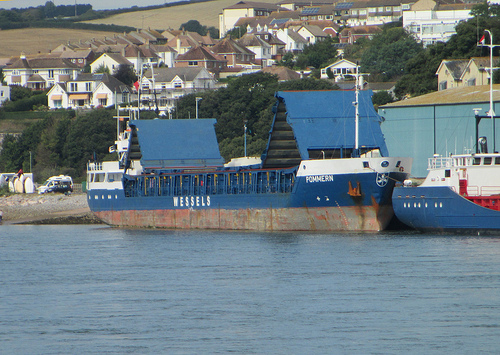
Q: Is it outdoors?
A: Yes, it is outdoors.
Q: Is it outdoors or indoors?
A: It is outdoors.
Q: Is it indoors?
A: No, it is outdoors.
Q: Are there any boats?
A: Yes, there is a boat.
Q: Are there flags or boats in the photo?
A: Yes, there is a boat.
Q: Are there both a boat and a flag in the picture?
A: Yes, there are both a boat and a flag.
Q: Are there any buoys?
A: No, there are no buoys.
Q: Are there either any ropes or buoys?
A: No, there are no buoys or ropes.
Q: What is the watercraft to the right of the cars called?
A: The watercraft is a boat.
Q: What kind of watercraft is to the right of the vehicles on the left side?
A: The watercraft is a boat.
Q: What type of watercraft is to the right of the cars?
A: The watercraft is a boat.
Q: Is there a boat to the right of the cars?
A: Yes, there is a boat to the right of the cars.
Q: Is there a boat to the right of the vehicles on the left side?
A: Yes, there is a boat to the right of the cars.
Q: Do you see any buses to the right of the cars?
A: No, there is a boat to the right of the cars.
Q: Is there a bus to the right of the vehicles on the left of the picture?
A: No, there is a boat to the right of the cars.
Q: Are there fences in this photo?
A: No, there are no fences.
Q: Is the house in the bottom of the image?
A: No, the house is in the top of the image.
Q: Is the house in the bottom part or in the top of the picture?
A: The house is in the top of the image.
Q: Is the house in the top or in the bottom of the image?
A: The house is in the top of the image.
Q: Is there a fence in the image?
A: No, there are no fences.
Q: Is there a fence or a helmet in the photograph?
A: No, there are no fences or helmets.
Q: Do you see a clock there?
A: No, there are no clocks.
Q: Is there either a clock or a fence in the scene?
A: No, there are no clocks or fences.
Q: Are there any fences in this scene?
A: No, there are no fences.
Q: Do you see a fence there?
A: No, there are no fences.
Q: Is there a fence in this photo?
A: No, there are no fences.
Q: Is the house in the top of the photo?
A: Yes, the house is in the top of the image.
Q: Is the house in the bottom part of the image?
A: No, the house is in the top of the image.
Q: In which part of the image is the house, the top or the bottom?
A: The house is in the top of the image.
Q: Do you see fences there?
A: No, there are no fences.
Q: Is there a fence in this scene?
A: No, there are no fences.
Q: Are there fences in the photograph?
A: No, there are no fences.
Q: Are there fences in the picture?
A: No, there are no fences.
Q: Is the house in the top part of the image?
A: Yes, the house is in the top of the image.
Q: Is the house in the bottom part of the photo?
A: No, the house is in the top of the image.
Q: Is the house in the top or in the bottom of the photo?
A: The house is in the top of the image.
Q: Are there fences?
A: No, there are no fences.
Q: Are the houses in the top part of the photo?
A: Yes, the houses are in the top of the image.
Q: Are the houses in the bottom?
A: No, the houses are in the top of the image.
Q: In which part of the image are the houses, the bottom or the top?
A: The houses are in the top of the image.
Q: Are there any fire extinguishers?
A: No, there are no fire extinguishers.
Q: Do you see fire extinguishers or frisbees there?
A: No, there are no fire extinguishers or frisbees.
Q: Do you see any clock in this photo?
A: No, there are no clocks.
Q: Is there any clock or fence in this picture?
A: No, there are no clocks or fences.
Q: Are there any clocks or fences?
A: No, there are no clocks or fences.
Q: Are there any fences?
A: No, there are no fences.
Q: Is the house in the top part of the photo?
A: Yes, the house is in the top of the image.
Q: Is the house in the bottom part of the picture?
A: No, the house is in the top of the image.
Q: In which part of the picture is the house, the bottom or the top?
A: The house is in the top of the image.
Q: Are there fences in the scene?
A: No, there are no fences.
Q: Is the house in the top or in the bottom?
A: The house is in the top of the image.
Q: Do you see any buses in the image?
A: No, there are no buses.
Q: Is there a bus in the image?
A: No, there are no buses.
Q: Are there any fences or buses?
A: No, there are no buses or fences.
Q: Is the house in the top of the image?
A: Yes, the house is in the top of the image.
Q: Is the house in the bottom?
A: No, the house is in the top of the image.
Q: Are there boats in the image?
A: Yes, there is a boat.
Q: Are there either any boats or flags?
A: Yes, there is a boat.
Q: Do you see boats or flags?
A: Yes, there is a boat.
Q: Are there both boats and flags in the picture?
A: Yes, there are both a boat and a flag.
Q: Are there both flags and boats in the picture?
A: Yes, there are both a boat and a flag.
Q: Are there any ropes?
A: No, there are no ropes.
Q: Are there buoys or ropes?
A: No, there are no ropes or buoys.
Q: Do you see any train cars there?
A: No, there are no train cars.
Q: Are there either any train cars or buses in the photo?
A: No, there are no train cars or buses.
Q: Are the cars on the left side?
A: Yes, the cars are on the left of the image.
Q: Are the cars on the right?
A: No, the cars are on the left of the image.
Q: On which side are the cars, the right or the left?
A: The cars are on the left of the image.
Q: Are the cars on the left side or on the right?
A: The cars are on the left of the image.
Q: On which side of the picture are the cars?
A: The cars are on the left of the image.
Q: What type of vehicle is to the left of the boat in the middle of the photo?
A: The vehicles are cars.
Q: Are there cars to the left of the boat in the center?
A: Yes, there are cars to the left of the boat.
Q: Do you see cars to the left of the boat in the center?
A: Yes, there are cars to the left of the boat.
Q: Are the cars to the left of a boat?
A: Yes, the cars are to the left of a boat.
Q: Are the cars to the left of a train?
A: No, the cars are to the left of a boat.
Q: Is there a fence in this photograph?
A: No, there are no fences.